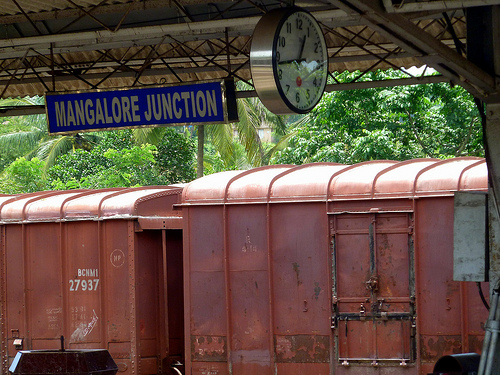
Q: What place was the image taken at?
A: It was taken at the train station.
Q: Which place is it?
A: It is a train station.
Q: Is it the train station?
A: Yes, it is the train station.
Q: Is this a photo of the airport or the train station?
A: It is showing the train station.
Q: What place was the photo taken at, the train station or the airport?
A: It was taken at the train station.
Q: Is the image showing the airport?
A: No, the picture is showing the train station.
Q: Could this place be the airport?
A: No, it is the train station.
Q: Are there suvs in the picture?
A: No, there are no suvs.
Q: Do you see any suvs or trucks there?
A: No, there are no suvs or trucks.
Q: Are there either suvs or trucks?
A: No, there are no suvs or trucks.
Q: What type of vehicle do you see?
A: The vehicle is a train car.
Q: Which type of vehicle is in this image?
A: The vehicle is a train car.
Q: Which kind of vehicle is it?
A: The vehicle is a train car.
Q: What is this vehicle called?
A: This is a train car.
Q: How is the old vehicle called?
A: The vehicle is a train car.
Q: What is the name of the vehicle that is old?
A: The vehicle is a train car.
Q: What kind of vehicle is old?
A: The vehicle is a train car.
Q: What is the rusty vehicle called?
A: The vehicle is a train car.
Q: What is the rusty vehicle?
A: The vehicle is a train car.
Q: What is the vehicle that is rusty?
A: The vehicle is a train car.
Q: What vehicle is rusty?
A: The vehicle is a train car.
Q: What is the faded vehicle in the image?
A: The vehicle is a train car.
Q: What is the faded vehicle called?
A: The vehicle is a train car.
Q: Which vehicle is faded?
A: The vehicle is a train car.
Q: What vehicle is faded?
A: The vehicle is a train car.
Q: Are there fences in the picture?
A: No, there are no fences.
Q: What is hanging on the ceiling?
A: The sign is hanging on the ceiling.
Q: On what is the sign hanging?
A: The sign is hanging on the ceiling.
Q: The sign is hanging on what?
A: The sign is hanging on the ceiling.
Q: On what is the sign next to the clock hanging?
A: The sign is hanging on the ceiling.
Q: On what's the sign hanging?
A: The sign is hanging on the ceiling.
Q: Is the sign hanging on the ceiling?
A: Yes, the sign is hanging on the ceiling.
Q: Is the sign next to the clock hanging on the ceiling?
A: Yes, the sign is hanging on the ceiling.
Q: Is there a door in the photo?
A: Yes, there is a door.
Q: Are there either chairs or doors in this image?
A: Yes, there is a door.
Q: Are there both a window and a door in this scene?
A: No, there is a door but no windows.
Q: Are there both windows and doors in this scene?
A: No, there is a door but no windows.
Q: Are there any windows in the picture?
A: No, there are no windows.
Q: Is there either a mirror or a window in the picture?
A: No, there are no windows or mirrors.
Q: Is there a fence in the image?
A: No, there are no fences.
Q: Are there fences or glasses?
A: No, there are no fences or glasses.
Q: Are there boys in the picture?
A: No, there are no boys.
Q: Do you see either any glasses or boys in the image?
A: No, there are no boys or glasses.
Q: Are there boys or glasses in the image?
A: No, there are no boys or glasses.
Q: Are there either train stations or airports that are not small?
A: No, there is a train station but it is small.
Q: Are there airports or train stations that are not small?
A: No, there is a train station but it is small.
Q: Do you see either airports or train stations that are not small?
A: No, there is a train station but it is small.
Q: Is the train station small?
A: Yes, the train station is small.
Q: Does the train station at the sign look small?
A: Yes, the train station is small.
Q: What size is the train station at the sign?
A: The train station is small.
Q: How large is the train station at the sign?
A: The train station is small.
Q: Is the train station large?
A: No, the train station is small.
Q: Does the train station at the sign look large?
A: No, the train station is small.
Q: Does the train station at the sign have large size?
A: No, the train station is small.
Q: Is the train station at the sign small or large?
A: The train station is small.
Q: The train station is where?
A: The train station is at the sign.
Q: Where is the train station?
A: The train station is at the sign.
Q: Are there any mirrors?
A: No, there are no mirrors.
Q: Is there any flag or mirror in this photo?
A: No, there are no mirrors or flags.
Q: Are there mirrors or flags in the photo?
A: No, there are no mirrors or flags.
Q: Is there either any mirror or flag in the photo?
A: No, there are no mirrors or flags.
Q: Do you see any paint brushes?
A: No, there are no paint brushes.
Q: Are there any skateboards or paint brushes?
A: No, there are no paint brushes or skateboards.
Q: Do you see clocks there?
A: Yes, there is a clock.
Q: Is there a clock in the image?
A: Yes, there is a clock.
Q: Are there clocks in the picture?
A: Yes, there is a clock.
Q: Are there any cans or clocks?
A: Yes, there is a clock.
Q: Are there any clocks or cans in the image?
A: Yes, there is a clock.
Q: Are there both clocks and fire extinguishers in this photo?
A: No, there is a clock but no fire extinguishers.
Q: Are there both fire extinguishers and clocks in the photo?
A: No, there is a clock but no fire extinguishers.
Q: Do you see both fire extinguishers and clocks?
A: No, there is a clock but no fire extinguishers.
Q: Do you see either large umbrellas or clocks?
A: Yes, there is a large clock.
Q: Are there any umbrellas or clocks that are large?
A: Yes, the clock is large.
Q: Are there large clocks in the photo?
A: Yes, there is a large clock.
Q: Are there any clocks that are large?
A: Yes, there is a large clock.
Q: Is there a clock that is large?
A: Yes, there is a clock that is large.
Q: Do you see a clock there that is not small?
A: Yes, there is a large clock.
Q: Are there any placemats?
A: No, there are no placemats.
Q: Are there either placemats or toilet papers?
A: No, there are no placemats or toilet papers.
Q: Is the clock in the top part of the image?
A: Yes, the clock is in the top of the image.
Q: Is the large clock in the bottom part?
A: No, the clock is in the top of the image.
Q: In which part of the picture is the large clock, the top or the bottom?
A: The clock is in the top of the image.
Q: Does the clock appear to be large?
A: Yes, the clock is large.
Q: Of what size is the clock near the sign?
A: The clock is large.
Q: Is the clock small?
A: No, the clock is large.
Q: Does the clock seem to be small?
A: No, the clock is large.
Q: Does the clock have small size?
A: No, the clock is large.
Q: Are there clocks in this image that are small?
A: No, there is a clock but it is large.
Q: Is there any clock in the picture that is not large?
A: No, there is a clock but it is large.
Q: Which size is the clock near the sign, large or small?
A: The clock is large.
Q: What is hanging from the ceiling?
A: The clock is hanging from the ceiling.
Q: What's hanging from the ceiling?
A: The clock is hanging from the ceiling.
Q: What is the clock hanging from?
A: The clock is hanging from the ceiling.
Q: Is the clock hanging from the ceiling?
A: Yes, the clock is hanging from the ceiling.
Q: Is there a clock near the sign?
A: Yes, there is a clock near the sign.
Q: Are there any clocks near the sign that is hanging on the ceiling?
A: Yes, there is a clock near the sign.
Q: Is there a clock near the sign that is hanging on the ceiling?
A: Yes, there is a clock near the sign.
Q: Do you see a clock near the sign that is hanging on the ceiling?
A: Yes, there is a clock near the sign.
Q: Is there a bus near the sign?
A: No, there is a clock near the sign.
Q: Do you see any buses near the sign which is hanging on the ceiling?
A: No, there is a clock near the sign.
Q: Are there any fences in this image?
A: No, there are no fences.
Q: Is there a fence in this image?
A: No, there are no fences.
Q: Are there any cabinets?
A: No, there are no cabinets.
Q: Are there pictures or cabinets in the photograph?
A: No, there are no cabinets or pictures.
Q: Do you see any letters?
A: Yes, there are letters.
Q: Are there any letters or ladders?
A: Yes, there are letters.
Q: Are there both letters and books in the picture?
A: No, there are letters but no books.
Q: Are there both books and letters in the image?
A: No, there are letters but no books.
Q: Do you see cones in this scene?
A: No, there are no cones.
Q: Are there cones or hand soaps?
A: No, there are no cones or hand soaps.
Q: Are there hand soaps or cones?
A: No, there are no cones or hand soaps.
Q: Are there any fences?
A: No, there are no fences.